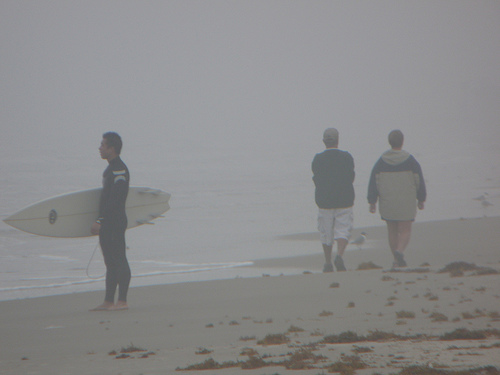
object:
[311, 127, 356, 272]
man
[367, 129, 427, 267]
woman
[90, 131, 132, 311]
surfer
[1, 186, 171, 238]
board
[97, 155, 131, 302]
wetsuit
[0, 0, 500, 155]
sky